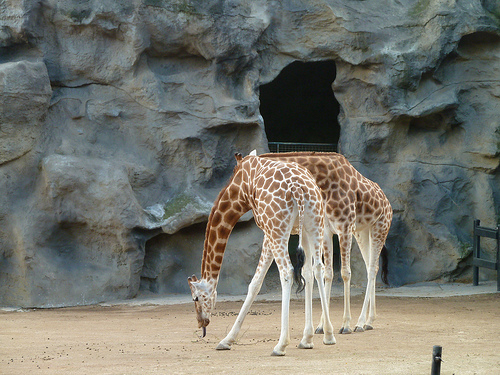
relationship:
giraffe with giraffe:
[183, 155, 335, 368] [229, 148, 392, 335]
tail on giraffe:
[289, 231, 312, 290] [182, 150, 324, 357]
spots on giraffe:
[188, 151, 325, 279] [183, 155, 335, 368]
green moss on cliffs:
[156, 189, 192, 219] [1, 0, 497, 299]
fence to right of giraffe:
[467, 198, 499, 301] [183, 155, 335, 368]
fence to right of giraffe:
[467, 198, 499, 301] [229, 148, 392, 335]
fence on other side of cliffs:
[467, 216, 499, 295] [5, 0, 497, 291]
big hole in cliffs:
[250, 54, 343, 154] [5, 0, 497, 291]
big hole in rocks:
[256, 54, 342, 154] [15, 40, 227, 225]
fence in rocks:
[268, 143, 338, 153] [1, 1, 497, 312]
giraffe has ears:
[171, 152, 367, 366] [181, 274, 205, 290]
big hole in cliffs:
[256, 54, 342, 154] [1, 0, 497, 299]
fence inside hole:
[268, 143, 338, 153] [250, 46, 360, 161]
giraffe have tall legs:
[229, 149, 390, 335] [262, 197, 294, 358]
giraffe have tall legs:
[229, 149, 390, 335] [216, 222, 273, 357]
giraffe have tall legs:
[229, 149, 390, 335] [302, 194, 337, 345]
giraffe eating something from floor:
[171, 149, 391, 331] [0, 293, 497, 374]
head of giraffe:
[180, 270, 219, 338] [150, 136, 402, 361]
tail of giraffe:
[294, 193, 304, 293] [183, 155, 335, 368]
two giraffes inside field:
[176, 124, 410, 366] [42, 304, 162, 370]